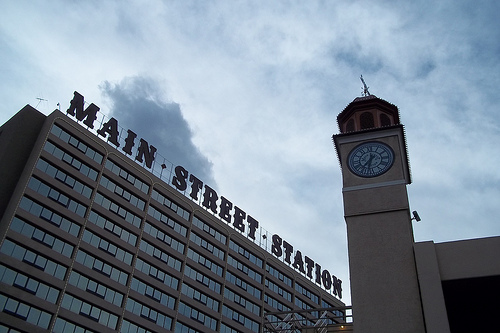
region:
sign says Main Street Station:
[54, 77, 385, 298]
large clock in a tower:
[311, 58, 438, 328]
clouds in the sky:
[4, 10, 498, 270]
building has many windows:
[14, 114, 345, 326]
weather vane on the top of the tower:
[331, 68, 398, 123]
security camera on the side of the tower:
[410, 205, 428, 230]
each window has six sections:
[48, 122, 106, 172]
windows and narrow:
[41, 118, 222, 292]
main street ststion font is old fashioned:
[50, 82, 342, 310]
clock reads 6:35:
[337, 132, 407, 200]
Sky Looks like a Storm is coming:
[41, 0, 495, 175]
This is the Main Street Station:
[64, 89, 351, 302]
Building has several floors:
[2, 86, 349, 331]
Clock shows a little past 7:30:
[345, 139, 397, 182]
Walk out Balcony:
[257, 300, 362, 330]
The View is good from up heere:
[322, 68, 411, 138]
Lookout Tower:
[350, 68, 377, 102]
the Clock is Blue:
[340, 135, 399, 181]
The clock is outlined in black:
[343, 138, 400, 180]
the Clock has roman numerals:
[342, 138, 401, 180]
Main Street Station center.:
[0, 86, 342, 331]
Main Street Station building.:
[2, 75, 497, 330]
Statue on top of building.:
[349, 73, 380, 96]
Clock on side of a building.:
[330, 74, 426, 181]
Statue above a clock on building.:
[334, 71, 413, 187]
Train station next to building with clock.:
[3, 87, 345, 331]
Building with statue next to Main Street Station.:
[5, 70, 498, 332]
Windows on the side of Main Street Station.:
[0, 91, 345, 331]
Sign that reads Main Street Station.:
[55, 90, 346, 307]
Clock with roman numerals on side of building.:
[337, 135, 405, 183]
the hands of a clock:
[358, 150, 375, 172]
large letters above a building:
[65, 83, 347, 299]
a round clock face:
[343, 136, 396, 184]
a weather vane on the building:
[355, 71, 373, 98]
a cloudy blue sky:
[1, 0, 499, 322]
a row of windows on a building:
[47, 119, 106, 167]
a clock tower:
[329, 72, 431, 332]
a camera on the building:
[407, 206, 424, 223]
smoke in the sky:
[91, 65, 226, 215]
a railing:
[256, 302, 351, 331]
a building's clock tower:
[324, 80, 429, 331]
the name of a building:
[61, 81, 349, 300]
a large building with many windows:
[0, 118, 327, 331]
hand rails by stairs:
[256, 301, 354, 331]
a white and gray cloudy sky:
[2, 2, 497, 207]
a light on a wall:
[324, 319, 356, 331]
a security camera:
[405, 199, 433, 238]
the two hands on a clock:
[359, 153, 381, 171]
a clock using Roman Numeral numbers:
[342, 141, 399, 183]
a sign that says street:
[168, 159, 270, 249]